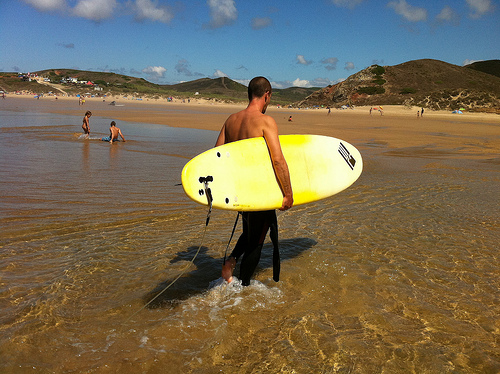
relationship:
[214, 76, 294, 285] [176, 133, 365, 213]
man has surfboard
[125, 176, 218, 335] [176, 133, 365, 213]
lanyard on surfboard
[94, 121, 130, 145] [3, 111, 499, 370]
person in water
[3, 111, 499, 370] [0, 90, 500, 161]
water by beach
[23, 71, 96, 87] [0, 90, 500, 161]
lot by beach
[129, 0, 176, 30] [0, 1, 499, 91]
cloud in sky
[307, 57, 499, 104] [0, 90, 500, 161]
hill by beach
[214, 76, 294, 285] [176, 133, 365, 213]
man carrying surfboard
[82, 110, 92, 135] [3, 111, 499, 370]
girl in water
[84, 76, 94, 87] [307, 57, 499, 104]
house by hill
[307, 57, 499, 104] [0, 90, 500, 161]
hill behind beach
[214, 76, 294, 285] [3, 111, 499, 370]
man in water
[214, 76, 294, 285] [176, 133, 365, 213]
man with a surfboard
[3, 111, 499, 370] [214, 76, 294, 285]
water by man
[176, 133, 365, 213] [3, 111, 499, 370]
surfboard by water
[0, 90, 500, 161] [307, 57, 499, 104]
beach by hill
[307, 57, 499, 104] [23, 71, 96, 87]
hill near lot